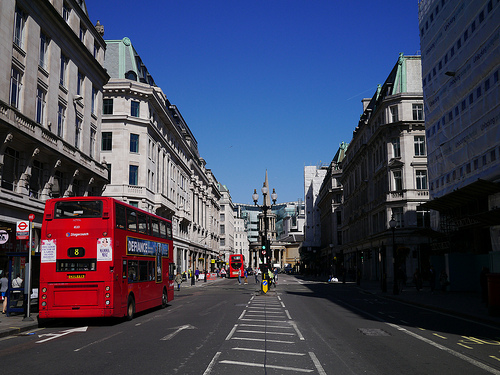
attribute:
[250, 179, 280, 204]
lights — three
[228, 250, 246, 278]
bus — red 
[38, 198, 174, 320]
bus — red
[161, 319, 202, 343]
arrow — painted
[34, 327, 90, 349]
arrow — painted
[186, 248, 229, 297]
people — several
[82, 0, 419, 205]
sky — blue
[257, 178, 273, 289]
lamp — street lamp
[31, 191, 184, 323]
bus — red, double-decker, close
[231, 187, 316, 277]
buildings — distant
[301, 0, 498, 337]
buildings — several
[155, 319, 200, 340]
arrow — white, painted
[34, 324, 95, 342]
arrow — white, painted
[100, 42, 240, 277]
buildings — several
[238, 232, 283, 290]
light — traffic light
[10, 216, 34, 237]
stop sign — red 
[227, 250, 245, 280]
bus — double decker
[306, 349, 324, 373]
line — white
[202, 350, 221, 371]
line — white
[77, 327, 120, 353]
line — white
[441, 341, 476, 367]
line — white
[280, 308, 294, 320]
line — white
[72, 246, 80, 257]
number — yellow